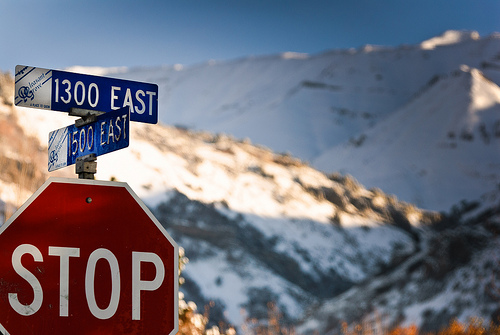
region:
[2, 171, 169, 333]
A stop sign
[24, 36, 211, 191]
A street sign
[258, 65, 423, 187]
Snow on the mountains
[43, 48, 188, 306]
Signs on a street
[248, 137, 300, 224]
Snow and rocks on the mountains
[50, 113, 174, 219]
East streets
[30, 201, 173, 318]
A red stop sign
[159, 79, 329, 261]
Snow caps on the mountains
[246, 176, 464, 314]
Rocks on the mountain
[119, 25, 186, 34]
Blue sky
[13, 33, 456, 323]
a street sign near some mountains.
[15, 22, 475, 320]
a street sign near some snowy mountains.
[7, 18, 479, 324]
a street sign near cold mountains.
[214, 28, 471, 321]
some amazing mountains in view.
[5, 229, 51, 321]
a letter "S" in white lettering on sign.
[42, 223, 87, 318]
a letter "T" in white lettering on sign.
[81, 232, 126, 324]
a letter "O" in white lettering on sign.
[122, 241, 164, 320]
a letter "P" in white lettering on sign.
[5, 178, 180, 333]
a red stop sign.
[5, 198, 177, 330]
sign reading the word "stop".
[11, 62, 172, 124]
Sign says 1300 EAST.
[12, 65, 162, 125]
1300 EAST sign is at top of the pole.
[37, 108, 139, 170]
Sign says 1500 EAST.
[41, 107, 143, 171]
1500 EAST sign is second on the pole.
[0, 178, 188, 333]
STOP sign is red and white.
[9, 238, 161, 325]
STOP is written in white.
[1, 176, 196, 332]
Sign is trimmed in white.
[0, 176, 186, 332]
STOP sign is third on pole.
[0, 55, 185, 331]
There are three signs posted.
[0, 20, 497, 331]
There's snow on the ground.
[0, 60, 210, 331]
Two blue signs over a red sign.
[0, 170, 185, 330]
A red stop sign.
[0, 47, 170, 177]
Two blue signs with white letters.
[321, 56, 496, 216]
A snow covered mountain.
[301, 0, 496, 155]
A blue sky over snow covered mountains.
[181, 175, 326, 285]
Partially snow covered mountain.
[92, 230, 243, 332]
Brown leaves behind a traffic sign.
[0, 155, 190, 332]
A red octagon shaped sign.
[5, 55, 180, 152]
Signs with the direction East on them.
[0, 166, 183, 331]
White letters on a red sign.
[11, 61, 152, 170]
two signs on pole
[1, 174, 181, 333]
stop sign under two signs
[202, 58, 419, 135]
snow covered mountain in background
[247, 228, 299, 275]
ground show through snow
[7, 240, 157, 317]
white letters on stop sign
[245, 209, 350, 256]
shadow of mountain on snow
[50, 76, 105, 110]
number on blue sign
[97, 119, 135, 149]
word on bottom sign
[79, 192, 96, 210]
bolt in stop sign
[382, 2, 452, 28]
dark blue daytime sky